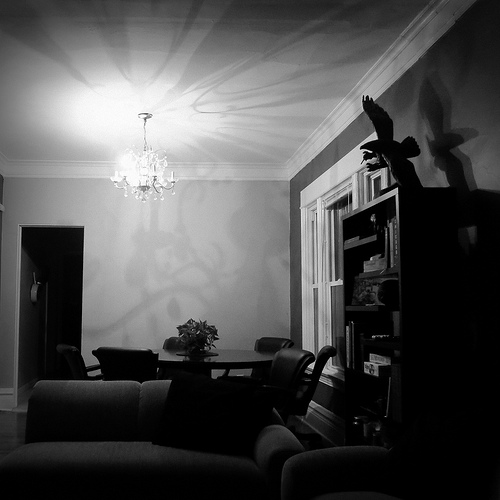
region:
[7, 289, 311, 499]
a couch with an arm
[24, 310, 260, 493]
a couch without an arm rest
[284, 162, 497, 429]
a tall book shelf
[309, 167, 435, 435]
a wood book shelf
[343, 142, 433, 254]
a statue on top of the book shelf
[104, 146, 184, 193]
a light hanging from the ceilling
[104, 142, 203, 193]
a chandlier hanging from the ceiling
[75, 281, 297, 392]
a dining room table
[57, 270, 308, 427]
a table with flowers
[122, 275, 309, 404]
a dining room table with flowers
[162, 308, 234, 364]
centerpiece of flowers on table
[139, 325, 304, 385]
rounded wooden dining table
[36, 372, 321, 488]
a small love seat couch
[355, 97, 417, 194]
a hawk on a bookshelf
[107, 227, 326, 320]
shadow of chandalier on wall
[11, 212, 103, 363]
entry way to another room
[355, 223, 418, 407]
bookshelf with items on each shelf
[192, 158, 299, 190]
white crown molding around room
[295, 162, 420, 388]
large bay window in room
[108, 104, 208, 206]
The chandelier is hanging from the ceiling.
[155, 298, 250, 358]
Flower pot in middle of table.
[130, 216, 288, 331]
Reflection of the chandelier shining on the wall.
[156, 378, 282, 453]
A big pillow on the sofa.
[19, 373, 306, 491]
A sofa in front of the dining table.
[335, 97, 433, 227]
A eagle figurine on top of the shelf.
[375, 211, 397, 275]
Books on the top shelf.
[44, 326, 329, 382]
Chairs around the table.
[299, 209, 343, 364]
A window next to the dining table.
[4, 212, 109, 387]
A doorway to another room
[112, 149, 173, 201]
chandiliers light is on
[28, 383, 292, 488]
blakc sofa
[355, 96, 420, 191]
an eagle statue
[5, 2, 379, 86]
shadow coming from the chandelier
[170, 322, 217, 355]
flowers in the table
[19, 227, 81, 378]
it is dark inside the kitchen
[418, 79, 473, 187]
shadow of the eagle statue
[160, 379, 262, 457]
pillow in the sofa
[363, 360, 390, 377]
color white box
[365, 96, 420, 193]
eagle in a sideway position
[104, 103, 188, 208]
chandelier lighting room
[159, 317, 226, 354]
flowers on table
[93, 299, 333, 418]
table with chairs strewn around it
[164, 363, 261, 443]
large pillow on couch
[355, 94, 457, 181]
bird statue on top of bookshelf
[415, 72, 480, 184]
bird statue casting shadow on wall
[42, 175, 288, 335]
chandelier casting shadows on wall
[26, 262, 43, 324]
pan hanging on wall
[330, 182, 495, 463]
large, wooden bookshelf with many books on it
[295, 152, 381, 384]
large windows uncovered